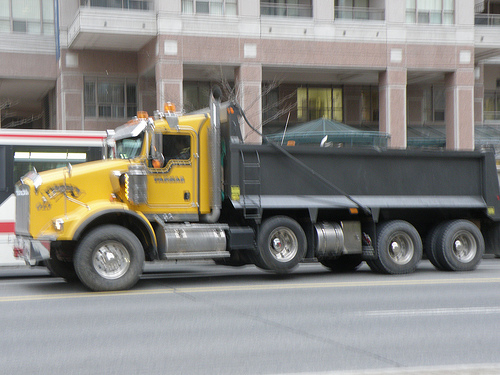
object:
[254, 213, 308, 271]
tire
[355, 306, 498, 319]
line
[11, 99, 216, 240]
truck cab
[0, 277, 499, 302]
line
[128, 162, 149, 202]
air filter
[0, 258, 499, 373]
road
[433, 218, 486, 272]
tire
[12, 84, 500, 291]
truck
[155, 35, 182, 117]
column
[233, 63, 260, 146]
column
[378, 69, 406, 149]
column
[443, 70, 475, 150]
column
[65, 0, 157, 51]
balcony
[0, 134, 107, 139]
stripe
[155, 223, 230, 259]
fuel tank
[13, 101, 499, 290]
dump truck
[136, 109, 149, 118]
lights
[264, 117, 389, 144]
tent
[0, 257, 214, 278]
curb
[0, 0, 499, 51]
second floor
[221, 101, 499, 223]
dump bed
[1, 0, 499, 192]
building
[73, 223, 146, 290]
tire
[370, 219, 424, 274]
tire